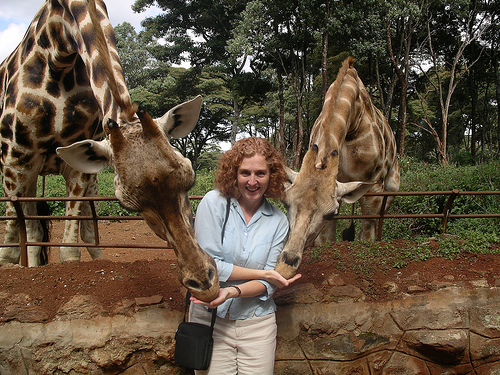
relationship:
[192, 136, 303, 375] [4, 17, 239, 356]
woman feeding giraffe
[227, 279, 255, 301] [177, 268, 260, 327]
bracelet on hand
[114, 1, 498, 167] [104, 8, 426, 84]
trees in background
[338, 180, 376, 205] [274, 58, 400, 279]
ear of giraffe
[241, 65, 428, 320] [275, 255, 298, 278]
giraffe has mouth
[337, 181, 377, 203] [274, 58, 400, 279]
ear on a giraffe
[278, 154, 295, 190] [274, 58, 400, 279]
ear on a giraffe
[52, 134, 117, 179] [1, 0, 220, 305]
ear on a giraffe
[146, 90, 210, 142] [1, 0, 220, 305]
ear on a giraffe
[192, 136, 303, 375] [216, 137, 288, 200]
woman with curly hair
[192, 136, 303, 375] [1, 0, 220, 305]
woman feeding giraffe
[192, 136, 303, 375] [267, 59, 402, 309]
woman feeding giraffe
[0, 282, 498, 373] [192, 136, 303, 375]
stone wall behind woman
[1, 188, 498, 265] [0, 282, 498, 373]
fence above stone wall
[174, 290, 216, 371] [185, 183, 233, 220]
bag hanging from shoulder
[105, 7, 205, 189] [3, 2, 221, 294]
trees behind giraffes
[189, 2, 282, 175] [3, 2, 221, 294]
trees behind giraffes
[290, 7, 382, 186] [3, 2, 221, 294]
trees behind giraffes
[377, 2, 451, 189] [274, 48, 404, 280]
trees behind giraffes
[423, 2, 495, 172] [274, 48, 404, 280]
trees behind giraffes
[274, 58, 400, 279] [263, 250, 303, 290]
giraffe eating out of hand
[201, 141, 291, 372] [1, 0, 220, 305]
woman feeding giraffe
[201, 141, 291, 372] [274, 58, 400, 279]
woman feeding giraffe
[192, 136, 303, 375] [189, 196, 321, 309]
woman wearing shirt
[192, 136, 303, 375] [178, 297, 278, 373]
woman wears pants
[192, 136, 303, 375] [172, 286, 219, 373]
woman wears bag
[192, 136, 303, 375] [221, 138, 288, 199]
woman has curly hair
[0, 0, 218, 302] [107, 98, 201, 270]
giraffe has head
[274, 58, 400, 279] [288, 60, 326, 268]
giraffe has head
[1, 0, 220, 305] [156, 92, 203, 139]
giraffe has ear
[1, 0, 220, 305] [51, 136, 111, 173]
giraffe has ear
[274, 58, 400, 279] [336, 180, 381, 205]
giraffe has ear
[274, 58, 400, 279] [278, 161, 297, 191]
giraffe has ear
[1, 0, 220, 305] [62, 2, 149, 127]
giraffe has neck